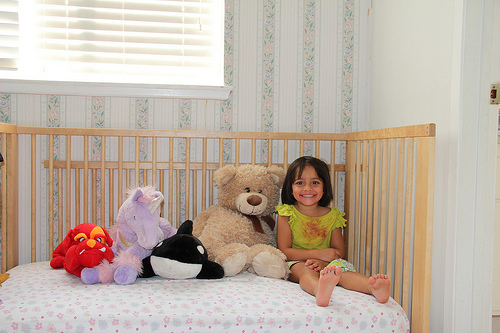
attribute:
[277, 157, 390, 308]
girl — little, smiling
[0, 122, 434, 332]
bed — wooden, brown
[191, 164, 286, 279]
teddy bear — brown, large, big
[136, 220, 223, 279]
whale — black, white, stuffed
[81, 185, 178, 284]
unicorn — purple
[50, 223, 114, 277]
bulldog — red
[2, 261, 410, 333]
mattress — white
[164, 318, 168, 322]
flower — pink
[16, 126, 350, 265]
headboard — wooden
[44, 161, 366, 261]
footboard — wooden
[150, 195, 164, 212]
horn — white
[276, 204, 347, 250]
blouse — yellow, green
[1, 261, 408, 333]
sheet — floral